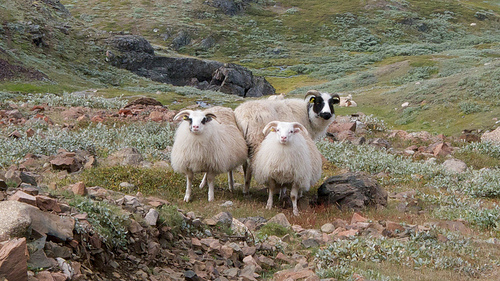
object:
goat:
[232, 89, 340, 193]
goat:
[251, 120, 321, 216]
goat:
[169, 105, 249, 202]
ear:
[294, 127, 299, 132]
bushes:
[460, 140, 499, 158]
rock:
[317, 173, 387, 207]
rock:
[197, 263, 206, 270]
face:
[312, 93, 334, 116]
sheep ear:
[268, 126, 276, 130]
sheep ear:
[182, 115, 189, 120]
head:
[303, 90, 340, 118]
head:
[260, 120, 310, 144]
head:
[173, 108, 223, 133]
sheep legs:
[207, 172, 215, 198]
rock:
[148, 110, 165, 120]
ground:
[1, 0, 499, 280]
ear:
[332, 99, 338, 104]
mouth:
[191, 127, 200, 131]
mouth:
[280, 139, 288, 142]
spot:
[290, 194, 296, 200]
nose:
[190, 124, 200, 128]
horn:
[302, 89, 320, 100]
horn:
[331, 92, 340, 99]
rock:
[0, 236, 28, 280]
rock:
[432, 142, 454, 156]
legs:
[206, 171, 215, 197]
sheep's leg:
[290, 182, 298, 209]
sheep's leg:
[266, 182, 272, 204]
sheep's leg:
[184, 172, 190, 195]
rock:
[142, 207, 159, 224]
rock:
[263, 210, 291, 229]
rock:
[319, 221, 336, 232]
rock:
[116, 181, 135, 191]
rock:
[220, 199, 238, 206]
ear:
[308, 96, 316, 103]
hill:
[0, 0, 499, 280]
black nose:
[317, 112, 332, 118]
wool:
[176, 135, 221, 156]